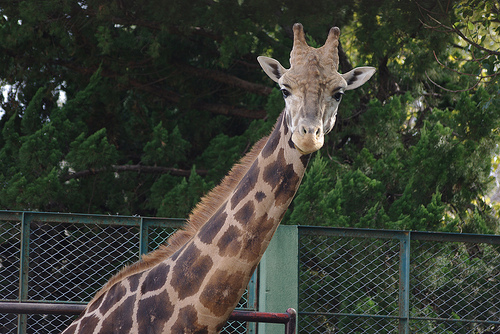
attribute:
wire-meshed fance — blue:
[406, 227, 498, 332]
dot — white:
[213, 285, 237, 303]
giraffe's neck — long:
[219, 156, 289, 271]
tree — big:
[345, 22, 498, 239]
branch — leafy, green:
[288, 150, 390, 227]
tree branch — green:
[0, 90, 185, 162]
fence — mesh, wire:
[1, 207, 499, 332]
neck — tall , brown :
[186, 134, 287, 292]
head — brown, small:
[254, 19, 377, 154]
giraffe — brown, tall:
[82, 14, 419, 316]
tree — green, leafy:
[0, 5, 498, 237]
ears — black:
[253, 51, 285, 82]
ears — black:
[340, 65, 380, 89]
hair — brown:
[92, 110, 279, 300]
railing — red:
[256, 296, 296, 329]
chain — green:
[290, 213, 490, 331]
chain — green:
[18, 224, 96, 304]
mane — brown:
[85, 106, 285, 308]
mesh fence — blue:
[0, 205, 497, 331]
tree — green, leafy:
[14, 45, 251, 240]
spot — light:
[226, 165, 268, 224]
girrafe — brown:
[64, 18, 377, 332]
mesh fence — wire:
[299, 229, 401, 326]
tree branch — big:
[97, 30, 264, 139]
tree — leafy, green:
[0, 0, 491, 208]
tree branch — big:
[40, 46, 210, 195]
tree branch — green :
[2, 3, 243, 143]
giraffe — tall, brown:
[51, 22, 381, 329]